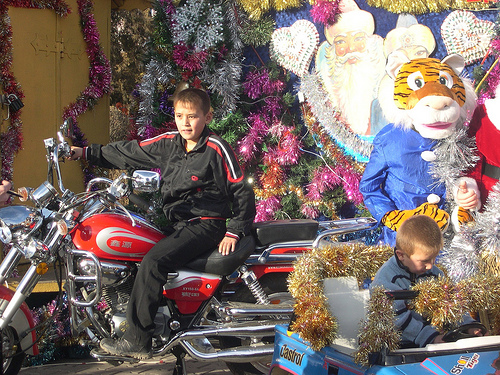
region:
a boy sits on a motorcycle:
[1, 83, 380, 373]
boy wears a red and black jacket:
[56, 82, 258, 361]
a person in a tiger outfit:
[356, 41, 476, 245]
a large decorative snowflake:
[165, 1, 231, 53]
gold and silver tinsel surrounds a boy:
[281, 225, 496, 374]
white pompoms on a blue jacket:
[417, 145, 442, 206]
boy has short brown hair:
[48, 82, 260, 373]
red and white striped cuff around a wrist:
[216, 220, 244, 257]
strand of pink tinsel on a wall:
[56, 2, 113, 190]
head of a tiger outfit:
[379, 43, 470, 148]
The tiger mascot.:
[360, 57, 470, 216]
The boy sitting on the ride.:
[381, 215, 460, 355]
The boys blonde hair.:
[397, 213, 441, 256]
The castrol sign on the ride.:
[275, 341, 303, 365]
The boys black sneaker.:
[95, 333, 154, 373]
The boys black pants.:
[125, 216, 228, 333]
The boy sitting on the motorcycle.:
[90, 90, 252, 372]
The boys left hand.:
[213, 225, 244, 256]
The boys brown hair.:
[171, 85, 211, 111]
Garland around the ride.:
[295, 238, 370, 345]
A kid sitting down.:
[62, 88, 256, 358]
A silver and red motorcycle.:
[0, 120, 377, 373]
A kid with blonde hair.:
[372, 211, 484, 348]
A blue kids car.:
[270, 271, 499, 373]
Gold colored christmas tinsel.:
[277, 237, 394, 352]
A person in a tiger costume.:
[360, 50, 475, 244]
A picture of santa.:
[315, 0, 387, 138]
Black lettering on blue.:
[278, 340, 308, 367]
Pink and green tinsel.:
[62, 0, 114, 149]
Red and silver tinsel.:
[0, 0, 75, 193]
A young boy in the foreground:
[365, 210, 496, 357]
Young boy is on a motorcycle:
[1, 74, 381, 374]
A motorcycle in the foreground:
[3, 117, 377, 374]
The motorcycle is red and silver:
[1, 109, 383, 372]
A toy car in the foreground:
[265, 228, 499, 373]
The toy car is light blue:
[248, 234, 496, 374]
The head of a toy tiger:
[367, 37, 488, 148]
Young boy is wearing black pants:
[95, 210, 247, 357]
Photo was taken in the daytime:
[6, 1, 498, 374]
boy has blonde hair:
[362, 200, 477, 351]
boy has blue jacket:
[356, 207, 488, 360]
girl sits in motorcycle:
[11, 82, 306, 358]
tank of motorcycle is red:
[74, 207, 161, 266]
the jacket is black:
[77, 127, 262, 243]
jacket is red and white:
[77, 130, 262, 244]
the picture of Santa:
[311, 2, 388, 119]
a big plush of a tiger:
[350, 40, 487, 227]